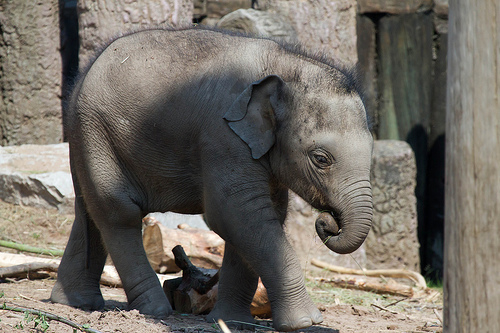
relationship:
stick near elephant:
[307, 259, 429, 299] [47, 25, 375, 332]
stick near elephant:
[304, 262, 428, 313] [47, 25, 375, 332]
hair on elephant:
[89, 7, 371, 114] [17, 17, 397, 327]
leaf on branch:
[9, 305, 41, 325] [10, 279, 90, 331]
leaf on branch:
[3, 304, 84, 333] [10, 279, 90, 331]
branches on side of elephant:
[161, 245, 222, 315] [47, 25, 375, 332]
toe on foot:
[295, 307, 323, 328] [255, 298, 333, 328]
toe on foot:
[305, 297, 327, 331] [255, 298, 333, 328]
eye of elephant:
[305, 144, 333, 171] [47, 25, 375, 332]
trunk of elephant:
[313, 175, 374, 255] [47, 25, 375, 332]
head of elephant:
[261, 42, 377, 254] [17, 17, 397, 327]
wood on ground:
[157, 246, 218, 310] [2, 140, 443, 329]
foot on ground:
[269, 300, 325, 329] [2, 140, 443, 329]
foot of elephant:
[269, 300, 325, 329] [47, 25, 375, 332]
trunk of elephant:
[313, 175, 374, 255] [33, 23, 436, 318]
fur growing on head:
[260, 42, 376, 122] [281, 68, 377, 255]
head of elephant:
[281, 68, 377, 255] [47, 25, 375, 332]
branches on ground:
[160, 240, 222, 315] [0, 196, 450, 331]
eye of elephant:
[309, 150, 331, 168] [47, 25, 375, 332]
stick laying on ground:
[307, 259, 429, 299] [0, 196, 450, 331]